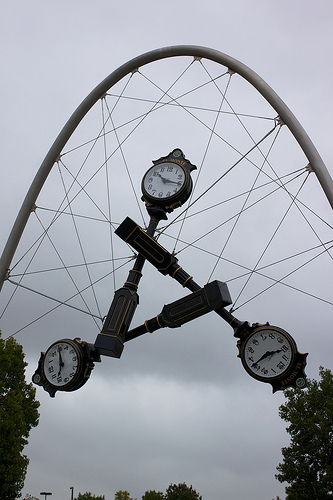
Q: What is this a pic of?
A: Clock structure.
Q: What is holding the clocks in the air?
A: The arch.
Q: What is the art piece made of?
A: Three clock towers.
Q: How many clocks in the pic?
A: 3.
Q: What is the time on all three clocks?
A: 10:15.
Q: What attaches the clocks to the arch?
A: Wires.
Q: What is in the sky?
A: Clouds.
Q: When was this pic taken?
A: During the day.